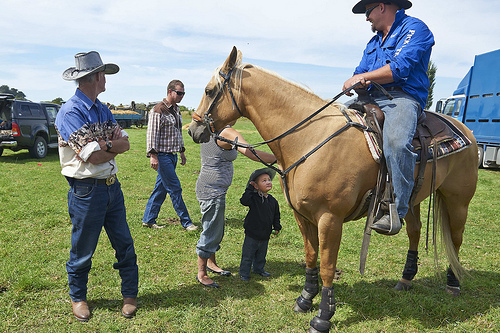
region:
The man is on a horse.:
[188, 0, 481, 332]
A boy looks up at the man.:
[237, 168, 278, 280]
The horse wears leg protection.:
[402, 249, 418, 280]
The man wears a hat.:
[353, 0, 415, 12]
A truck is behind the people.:
[0, 95, 53, 156]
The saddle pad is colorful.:
[437, 138, 465, 155]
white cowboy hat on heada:
[50, 53, 124, 93]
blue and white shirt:
[51, 103, 126, 171]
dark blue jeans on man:
[57, 178, 134, 298]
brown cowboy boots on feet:
[60, 298, 151, 320]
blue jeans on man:
[127, 146, 197, 231]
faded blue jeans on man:
[354, 95, 424, 233]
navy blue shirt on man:
[350, 18, 422, 93]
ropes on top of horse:
[182, 75, 360, 173]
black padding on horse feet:
[278, 272, 345, 332]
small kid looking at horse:
[237, 166, 284, 280]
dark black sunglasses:
[172, 88, 187, 95]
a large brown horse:
[188, 42, 483, 332]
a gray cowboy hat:
[57, 51, 119, 87]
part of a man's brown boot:
[69, 295, 95, 316]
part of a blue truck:
[439, 45, 499, 163]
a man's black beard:
[368, 22, 378, 32]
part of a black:
[0, 86, 58, 156]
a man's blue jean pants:
[142, 153, 194, 223]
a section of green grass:
[163, 285, 263, 331]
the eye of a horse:
[204, 84, 218, 99]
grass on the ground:
[161, 292, 195, 325]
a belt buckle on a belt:
[96, 171, 126, 192]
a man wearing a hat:
[57, 52, 121, 82]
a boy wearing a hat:
[244, 170, 280, 195]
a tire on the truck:
[33, 129, 49, 162]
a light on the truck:
[8, 116, 25, 146]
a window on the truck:
[22, 102, 40, 114]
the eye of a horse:
[201, 80, 226, 111]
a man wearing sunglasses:
[353, 4, 388, 28]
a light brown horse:
[187, 46, 481, 331]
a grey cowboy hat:
[60, 50, 120, 82]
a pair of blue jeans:
[65, 179, 139, 304]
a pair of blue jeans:
[143, 152, 196, 227]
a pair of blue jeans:
[339, 94, 416, 219]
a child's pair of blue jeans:
[240, 237, 269, 273]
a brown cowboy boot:
[69, 296, 91, 321]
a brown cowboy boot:
[119, 296, 138, 318]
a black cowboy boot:
[370, 214, 402, 231]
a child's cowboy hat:
[246, 167, 275, 192]